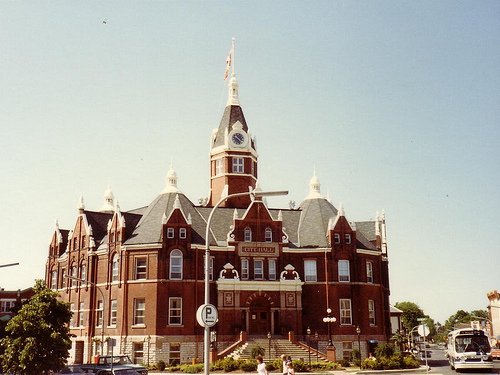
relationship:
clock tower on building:
[204, 39, 258, 153] [38, 39, 388, 362]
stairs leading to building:
[221, 334, 322, 372] [26, 50, 429, 373]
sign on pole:
[196, 304, 219, 327] [200, 182, 254, 372]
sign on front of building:
[231, 235, 300, 262] [46, 173, 410, 339]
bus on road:
[443, 327, 496, 372] [433, 344, 498, 371]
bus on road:
[443, 327, 496, 372] [416, 341, 498, 373]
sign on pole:
[176, 280, 251, 340] [202, 195, 229, 369]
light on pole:
[138, 183, 310, 365] [174, 201, 245, 319]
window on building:
[121, 288, 152, 338] [47, 55, 413, 366]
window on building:
[157, 244, 214, 301] [61, 47, 388, 371]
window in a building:
[335, 255, 350, 283] [47, 55, 413, 366]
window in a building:
[303, 258, 319, 287] [25, 27, 416, 342]